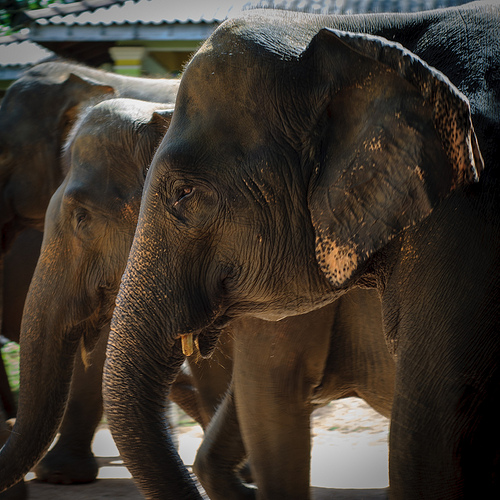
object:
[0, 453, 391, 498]
shadow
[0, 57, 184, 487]
elephant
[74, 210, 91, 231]
eye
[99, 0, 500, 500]
elephant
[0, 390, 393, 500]
ground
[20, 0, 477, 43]
roof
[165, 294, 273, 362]
mouth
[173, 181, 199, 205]
eye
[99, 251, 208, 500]
trunk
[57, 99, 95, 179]
elephant hair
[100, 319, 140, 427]
bad-sentence-(not dirt)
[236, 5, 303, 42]
light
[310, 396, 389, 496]
dirt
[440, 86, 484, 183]
dirt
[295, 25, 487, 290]
ear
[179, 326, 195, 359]
short tusk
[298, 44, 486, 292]
dirt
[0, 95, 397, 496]
elephant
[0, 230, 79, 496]
trunk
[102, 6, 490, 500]
head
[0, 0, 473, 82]
house